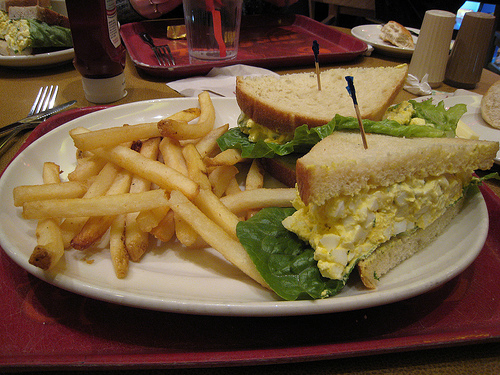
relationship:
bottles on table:
[407, 9, 498, 90] [11, 82, 37, 114]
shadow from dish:
[23, 272, 484, 371] [0, 97, 491, 316]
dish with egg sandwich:
[0, 97, 491, 316] [236, 62, 499, 290]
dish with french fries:
[0, 97, 491, 316] [13, 91, 303, 296]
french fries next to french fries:
[13, 91, 303, 296] [13, 91, 303, 296]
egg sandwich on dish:
[238, 62, 499, 304] [0, 97, 491, 316]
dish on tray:
[0, 97, 491, 316] [1, 97, 498, 373]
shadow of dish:
[23, 262, 476, 351] [0, 97, 491, 316]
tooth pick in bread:
[343, 75, 370, 151] [297, 126, 498, 203]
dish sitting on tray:
[3, 97, 491, 307] [1, 97, 498, 373]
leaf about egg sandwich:
[235, 171, 497, 299] [236, 62, 499, 290]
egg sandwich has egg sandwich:
[236, 62, 499, 290] [236, 62, 499, 290]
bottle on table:
[66, 6, 148, 108] [4, 4, 498, 373]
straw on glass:
[206, 0, 228, 59] [184, 7, 245, 63]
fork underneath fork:
[4, 81, 59, 166] [0, 84, 79, 158]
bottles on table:
[407, 9, 498, 90] [39, 29, 496, 117]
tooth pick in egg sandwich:
[343, 75, 370, 151] [236, 62, 499, 290]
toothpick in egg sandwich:
[310, 40, 321, 90] [236, 62, 499, 290]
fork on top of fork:
[0, 84, 79, 158] [1, 97, 76, 136]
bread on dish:
[256, 63, 402, 112] [0, 97, 491, 316]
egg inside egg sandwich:
[284, 187, 425, 259] [236, 62, 499, 290]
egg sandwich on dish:
[236, 62, 499, 290] [21, 85, 489, 315]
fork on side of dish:
[0, 84, 79, 158] [21, 85, 489, 315]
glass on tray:
[179, 2, 245, 68] [1, 97, 498, 373]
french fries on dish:
[13, 91, 303, 296] [0, 97, 491, 316]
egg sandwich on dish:
[236, 62, 499, 290] [0, 97, 491, 316]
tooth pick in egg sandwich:
[338, 68, 382, 158] [236, 62, 499, 290]